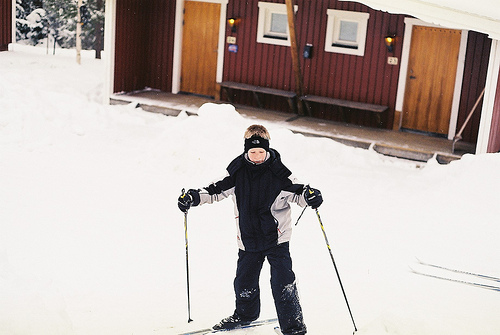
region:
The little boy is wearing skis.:
[162, 110, 367, 334]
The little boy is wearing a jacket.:
[168, 115, 378, 332]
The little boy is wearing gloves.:
[173, 113, 370, 334]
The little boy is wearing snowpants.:
[158, 112, 363, 334]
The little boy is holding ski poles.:
[170, 113, 365, 333]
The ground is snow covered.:
[0, 45, 499, 333]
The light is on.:
[378, 13, 400, 59]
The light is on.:
[223, 13, 245, 38]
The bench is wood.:
[210, 65, 298, 130]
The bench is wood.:
[299, 90, 396, 131]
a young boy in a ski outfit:
[165, 124, 395, 333]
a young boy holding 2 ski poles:
[171, 121, 360, 328]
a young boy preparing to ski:
[164, 115, 371, 334]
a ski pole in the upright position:
[167, 170, 207, 332]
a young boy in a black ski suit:
[175, 114, 369, 330]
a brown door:
[162, 2, 239, 104]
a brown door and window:
[162, 3, 300, 108]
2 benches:
[220, 73, 390, 130]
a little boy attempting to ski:
[152, 119, 372, 329]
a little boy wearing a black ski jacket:
[167, 117, 337, 246]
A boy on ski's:
[148, 95, 370, 332]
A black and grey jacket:
[222, 155, 304, 252]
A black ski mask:
[235, 126, 275, 169]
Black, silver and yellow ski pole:
[314, 209, 361, 332]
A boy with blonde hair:
[236, 124, 275, 172]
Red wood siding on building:
[226, 3, 385, 116]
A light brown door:
[406, 15, 457, 133]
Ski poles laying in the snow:
[402, 247, 494, 299]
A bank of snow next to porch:
[100, 104, 408, 214]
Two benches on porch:
[218, 78, 388, 132]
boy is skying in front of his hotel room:
[226, 143, 279, 164]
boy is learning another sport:
[233, 134, 279, 164]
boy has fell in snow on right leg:
[268, 286, 323, 331]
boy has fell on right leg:
[226, 288, 264, 310]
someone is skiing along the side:
[413, 254, 498, 292]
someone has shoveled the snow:
[441, 90, 483, 144]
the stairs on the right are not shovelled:
[371, 150, 437, 167]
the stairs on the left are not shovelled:
[133, 99, 189, 116]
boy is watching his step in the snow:
[210, 320, 315, 332]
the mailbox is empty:
[293, 40, 320, 65]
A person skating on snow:
[143, 132, 340, 321]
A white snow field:
[334, 228, 406, 331]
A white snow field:
[327, 162, 426, 217]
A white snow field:
[429, 160, 499, 223]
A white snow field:
[60, 259, 185, 312]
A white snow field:
[2, 183, 62, 294]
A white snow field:
[87, 117, 194, 178]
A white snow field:
[1, 90, 53, 197]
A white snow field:
[1, 42, 93, 117]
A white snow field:
[190, 93, 308, 165]